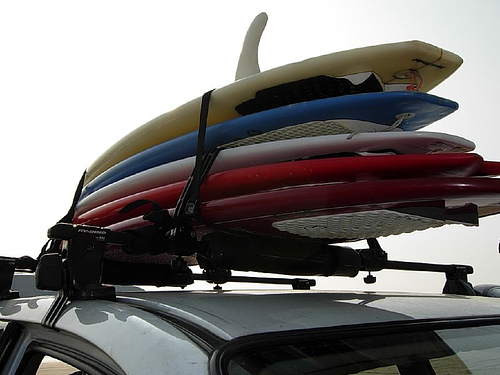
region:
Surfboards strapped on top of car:
[2, 15, 499, 374]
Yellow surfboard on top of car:
[52, 11, 469, 100]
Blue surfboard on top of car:
[71, 88, 473, 173]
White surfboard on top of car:
[61, 128, 489, 184]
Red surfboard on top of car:
[71, 154, 498, 212]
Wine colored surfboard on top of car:
[85, 181, 499, 221]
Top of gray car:
[6, 281, 493, 367]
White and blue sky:
[38, 3, 499, 274]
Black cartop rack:
[33, 218, 478, 302]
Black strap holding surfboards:
[147, 80, 252, 258]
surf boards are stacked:
[115, 130, 209, 262]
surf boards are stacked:
[125, 99, 356, 363]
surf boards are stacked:
[179, 80, 321, 287]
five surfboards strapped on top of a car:
[66, 10, 498, 242]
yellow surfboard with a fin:
[159, 10, 451, 99]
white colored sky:
[11, 15, 172, 88]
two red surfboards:
[43, 152, 497, 253]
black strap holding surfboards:
[181, 79, 240, 279]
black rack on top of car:
[44, 217, 491, 289]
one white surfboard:
[46, 135, 456, 209]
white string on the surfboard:
[378, 104, 414, 135]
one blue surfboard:
[58, 85, 463, 202]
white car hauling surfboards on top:
[2, 272, 499, 369]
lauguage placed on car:
[66, 42, 489, 237]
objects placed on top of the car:
[65, 29, 460, 276]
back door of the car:
[18, 347, 89, 370]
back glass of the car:
[18, 332, 68, 372]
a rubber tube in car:
[151, 310, 253, 373]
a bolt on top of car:
[353, 274, 386, 295]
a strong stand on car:
[87, 245, 481, 297]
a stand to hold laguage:
[19, 248, 493, 294]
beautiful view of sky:
[45, 32, 498, 237]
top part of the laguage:
[223, 15, 303, 83]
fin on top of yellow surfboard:
[210, 0, 297, 87]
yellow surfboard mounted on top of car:
[86, 32, 453, 128]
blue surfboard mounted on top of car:
[78, 82, 470, 151]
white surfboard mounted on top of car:
[72, 128, 497, 173]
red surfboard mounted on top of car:
[64, 142, 473, 220]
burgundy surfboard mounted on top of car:
[81, 193, 497, 248]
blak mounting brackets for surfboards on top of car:
[33, 167, 487, 329]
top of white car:
[61, 266, 417, 374]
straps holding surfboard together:
[171, 56, 228, 282]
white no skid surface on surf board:
[288, 187, 480, 252]